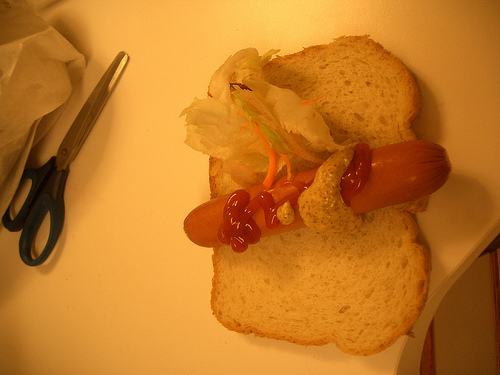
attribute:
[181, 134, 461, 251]
sausage — Brown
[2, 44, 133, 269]
scissors — small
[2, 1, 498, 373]
white table — wooden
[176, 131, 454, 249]
hotdog — prepared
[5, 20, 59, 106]
napkin — white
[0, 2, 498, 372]
table — wooden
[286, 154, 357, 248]
mustard — brown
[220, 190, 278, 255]
sauce — red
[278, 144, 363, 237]
mustard — spicy